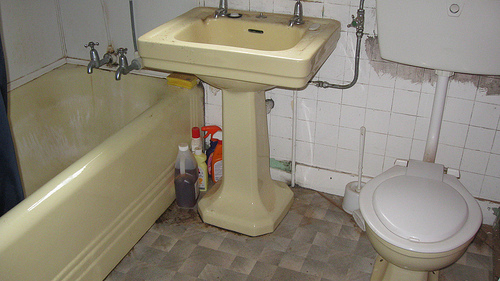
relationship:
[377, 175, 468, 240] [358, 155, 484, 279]
lid on top toilet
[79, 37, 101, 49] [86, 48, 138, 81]
handle on faucet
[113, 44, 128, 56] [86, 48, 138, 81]
handle on faucet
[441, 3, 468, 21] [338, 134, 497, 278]
button on toilet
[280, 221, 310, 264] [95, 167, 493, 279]
tiles on floor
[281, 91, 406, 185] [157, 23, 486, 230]
tiles on wall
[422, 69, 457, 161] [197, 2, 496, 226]
pipe on wall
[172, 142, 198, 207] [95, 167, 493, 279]
bottle on floor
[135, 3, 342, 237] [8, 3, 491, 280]
sink in bathroom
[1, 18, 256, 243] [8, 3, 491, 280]
bathtub in bathroom